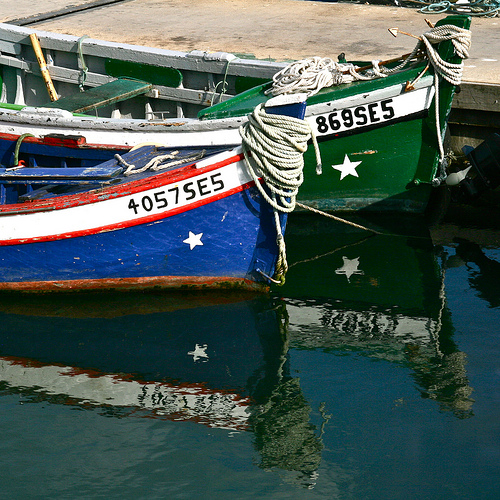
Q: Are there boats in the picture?
A: Yes, there is a boat.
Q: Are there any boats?
A: Yes, there is a boat.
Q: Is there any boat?
A: Yes, there is a boat.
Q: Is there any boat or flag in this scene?
A: Yes, there is a boat.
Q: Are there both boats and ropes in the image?
A: Yes, there are both a boat and a rope.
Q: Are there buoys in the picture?
A: No, there are no buoys.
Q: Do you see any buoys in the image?
A: No, there are no buoys.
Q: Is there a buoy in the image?
A: No, there are no buoys.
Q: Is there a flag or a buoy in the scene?
A: No, there are no buoys or flags.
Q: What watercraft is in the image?
A: The watercraft is a boat.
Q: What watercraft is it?
A: The watercraft is a boat.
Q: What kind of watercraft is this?
A: This is a boat.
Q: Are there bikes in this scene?
A: No, there are no bikes.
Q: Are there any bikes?
A: No, there are no bikes.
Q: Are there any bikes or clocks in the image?
A: No, there are no bikes or clocks.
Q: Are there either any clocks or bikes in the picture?
A: No, there are no bikes or clocks.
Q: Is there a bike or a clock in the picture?
A: No, there are no bikes or clocks.